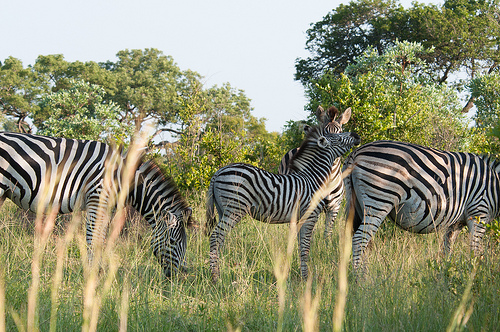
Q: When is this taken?
A: During the daytime.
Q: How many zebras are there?
A: Four.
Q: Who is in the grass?
A: Zebras.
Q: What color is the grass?
A: Green.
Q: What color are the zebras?
A: Black and white.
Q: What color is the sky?
A: Blue.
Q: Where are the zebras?
A: In a field.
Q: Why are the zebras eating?
A: They are hungry.